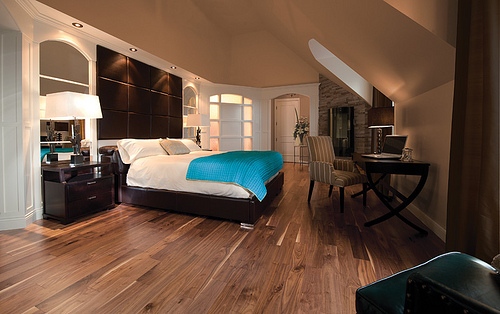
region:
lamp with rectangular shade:
[41, 85, 125, 227]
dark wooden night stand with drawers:
[26, 143, 143, 241]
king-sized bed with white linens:
[108, 133, 293, 228]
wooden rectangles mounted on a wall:
[87, 28, 204, 157]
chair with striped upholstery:
[303, 133, 368, 217]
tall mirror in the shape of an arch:
[35, 35, 97, 168]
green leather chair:
[351, 219, 497, 309]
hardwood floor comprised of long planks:
[33, 215, 333, 305]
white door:
[267, 87, 317, 164]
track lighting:
[61, 11, 208, 91]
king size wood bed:
[105, 138, 290, 220]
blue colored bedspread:
[186, 148, 286, 196]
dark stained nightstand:
[46, 158, 127, 226]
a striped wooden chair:
[308, 127, 368, 213]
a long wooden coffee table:
[353, 152, 433, 233]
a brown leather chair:
[358, 243, 498, 309]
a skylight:
[305, 31, 401, 103]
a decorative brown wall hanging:
[93, 35, 184, 145]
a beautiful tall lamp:
[65, 90, 101, 157]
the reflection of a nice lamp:
[42, 91, 67, 160]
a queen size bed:
[104, 137, 288, 225]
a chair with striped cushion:
[302, 130, 369, 210]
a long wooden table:
[357, 148, 432, 240]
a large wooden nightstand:
[47, 160, 118, 226]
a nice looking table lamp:
[42, 87, 104, 161]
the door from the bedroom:
[268, 94, 310, 161]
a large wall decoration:
[95, 47, 187, 140]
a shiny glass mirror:
[38, 37, 89, 147]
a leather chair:
[354, 235, 499, 311]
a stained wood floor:
[115, 208, 355, 311]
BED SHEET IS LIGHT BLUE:
[183, 140, 318, 231]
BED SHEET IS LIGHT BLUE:
[162, 102, 290, 249]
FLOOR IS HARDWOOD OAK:
[111, 234, 132, 276]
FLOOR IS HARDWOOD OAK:
[73, 182, 253, 311]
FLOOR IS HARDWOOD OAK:
[143, 211, 200, 290]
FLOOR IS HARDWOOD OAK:
[231, 242, 273, 281]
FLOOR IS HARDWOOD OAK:
[165, 235, 248, 303]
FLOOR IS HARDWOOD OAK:
[220, 232, 342, 308]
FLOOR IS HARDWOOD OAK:
[215, 247, 310, 297]